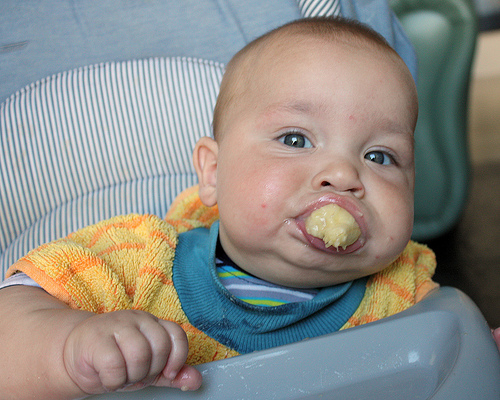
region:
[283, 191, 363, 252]
The baby has food stuffed in mouth.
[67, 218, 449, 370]
The baby have towel around him.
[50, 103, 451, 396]
The baby is eating.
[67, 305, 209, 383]
The baby hand is balled up.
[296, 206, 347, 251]
The food is yellow.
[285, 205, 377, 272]
The baby mouth is open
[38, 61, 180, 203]
The chair has stripes.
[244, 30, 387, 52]
The baby has little hair.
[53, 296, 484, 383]
The baby hand is on the blue object.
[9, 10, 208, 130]
The chair is blue and white.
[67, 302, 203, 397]
Little hand with fingers clenched into a fist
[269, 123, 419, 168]
Bright eyes of a child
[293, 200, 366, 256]
Food stuffed in the mouth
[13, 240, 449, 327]
Yellow towel wrapped around the neck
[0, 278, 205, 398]
Little arm with a clenched fist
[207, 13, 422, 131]
Short trimmed dark hair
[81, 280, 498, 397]
Light blue colored plastic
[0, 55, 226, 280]
White stripped blue clothing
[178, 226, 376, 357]
Blue collar neck of a shirt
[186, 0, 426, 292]
Head of a small baby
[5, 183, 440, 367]
baby wearing orange and yellow bib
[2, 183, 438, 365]
terrycloth bib with blue stretch neckline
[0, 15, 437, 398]
baby with large portion of banana in mouth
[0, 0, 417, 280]
light blue and white high chair cushion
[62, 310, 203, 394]
sticky fingers of baby's right hand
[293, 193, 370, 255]
mouth full of mushy banana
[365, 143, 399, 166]
baby's beautiful blue left eye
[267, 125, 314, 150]
baby's beautiful blue left eye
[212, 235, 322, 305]
baby's multi-colored shirt under bib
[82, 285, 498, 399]
plastic tray of baby's high chair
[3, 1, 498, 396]
a baby in a high chair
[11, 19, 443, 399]
the baby is wearing a bib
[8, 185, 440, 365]
the bib is blue and yellow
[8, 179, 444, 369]
the bib is striped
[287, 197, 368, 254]
food in the baby's mouth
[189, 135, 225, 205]
the baby has an ear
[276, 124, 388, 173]
the baby has gray eyes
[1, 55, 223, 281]
the high chair has stripes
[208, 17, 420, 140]
the baby has short hair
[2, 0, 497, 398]
the high chair is blue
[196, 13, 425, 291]
a baby spitting out food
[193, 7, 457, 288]
a baby eating food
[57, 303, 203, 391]
the hand on a baby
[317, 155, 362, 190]
the nose on a baby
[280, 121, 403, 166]
the eyes on a baby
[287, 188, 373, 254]
the mouth on a baby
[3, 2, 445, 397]
a baby in a baby chair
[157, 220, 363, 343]
a blue shirt collar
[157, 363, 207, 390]
the thumb on a baby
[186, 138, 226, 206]
the ear on a baby